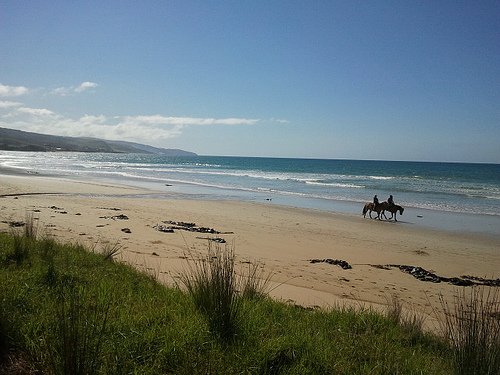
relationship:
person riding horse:
[371, 194, 381, 211] [363, 194, 388, 219]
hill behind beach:
[3, 127, 201, 160] [4, 173, 495, 337]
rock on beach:
[166, 217, 197, 230] [4, 173, 495, 337]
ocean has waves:
[16, 153, 500, 233] [86, 156, 398, 183]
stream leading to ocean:
[21, 187, 254, 205] [16, 153, 500, 233]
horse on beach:
[378, 204, 405, 219] [4, 173, 495, 337]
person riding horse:
[385, 194, 397, 205] [378, 204, 405, 219]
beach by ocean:
[4, 173, 495, 337] [16, 153, 500, 233]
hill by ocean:
[3, 127, 201, 160] [16, 153, 500, 233]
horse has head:
[363, 194, 388, 219] [383, 198, 391, 213]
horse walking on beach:
[363, 194, 388, 219] [4, 173, 495, 337]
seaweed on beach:
[309, 255, 354, 273] [4, 173, 495, 337]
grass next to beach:
[174, 233, 296, 345] [4, 173, 495, 337]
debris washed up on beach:
[163, 180, 176, 189] [4, 173, 495, 337]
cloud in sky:
[52, 77, 103, 96] [1, 2, 500, 165]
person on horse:
[371, 194, 381, 211] [363, 194, 388, 219]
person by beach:
[371, 194, 381, 211] [4, 173, 495, 337]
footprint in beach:
[369, 278, 378, 287] [4, 173, 495, 337]